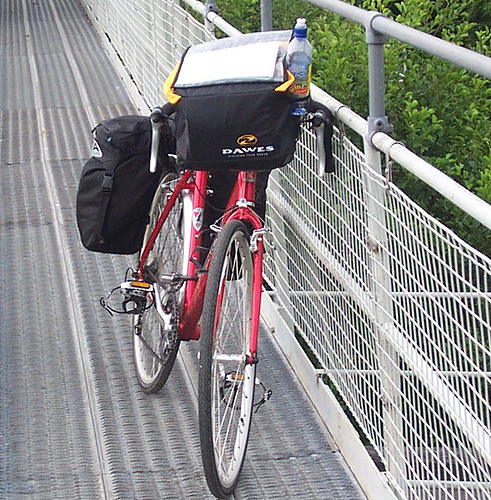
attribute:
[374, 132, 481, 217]
pipe — white, metal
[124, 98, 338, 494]
bike — pink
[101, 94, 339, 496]
bicycle — red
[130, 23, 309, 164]
bag — black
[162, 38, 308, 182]
bag — open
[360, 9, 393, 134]
pole — gray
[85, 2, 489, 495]
fence — white, long, metal, rusted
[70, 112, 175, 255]
bag — black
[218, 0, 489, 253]
leaves — green